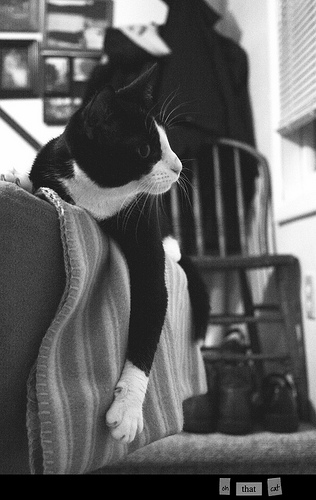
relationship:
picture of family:
[38, 48, 100, 124] [49, 55, 97, 113]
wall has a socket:
[223, 1, 314, 431] [302, 275, 314, 323]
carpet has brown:
[89, 432, 314, 475] [89, 425, 314, 476]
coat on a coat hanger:
[154, 2, 259, 256] [147, 2, 219, 32]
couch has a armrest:
[3, 177, 207, 478] [5, 175, 56, 479]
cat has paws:
[30, 62, 212, 443] [106, 378, 145, 444]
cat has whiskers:
[30, 62, 212, 443] [133, 88, 180, 223]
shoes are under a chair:
[218, 363, 298, 435] [169, 139, 309, 419]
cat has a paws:
[30, 62, 212, 443] [106, 378, 145, 444]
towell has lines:
[23, 183, 185, 473] [50, 203, 207, 478]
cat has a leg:
[30, 62, 212, 443] [158, 237, 183, 262]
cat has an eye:
[30, 62, 212, 443] [136, 139, 155, 157]